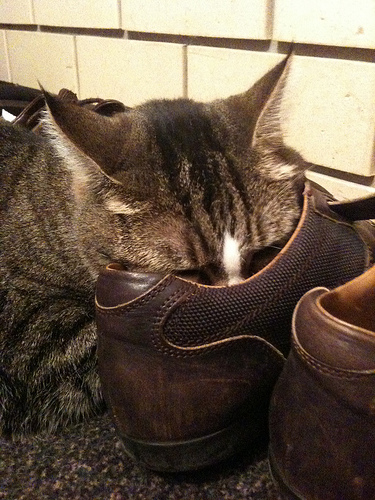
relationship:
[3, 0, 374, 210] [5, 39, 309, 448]
wall behind cat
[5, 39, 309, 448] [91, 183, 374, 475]
cat sniffing shoe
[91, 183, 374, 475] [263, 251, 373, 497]
shoe next to shoe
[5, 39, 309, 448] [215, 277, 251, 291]
cat has nose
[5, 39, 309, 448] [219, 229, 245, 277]
cat has mark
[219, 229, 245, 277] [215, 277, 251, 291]
mark above nose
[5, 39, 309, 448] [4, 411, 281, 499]
cat on rug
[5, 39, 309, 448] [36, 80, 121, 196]
cat has ear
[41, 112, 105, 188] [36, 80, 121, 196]
hair in ear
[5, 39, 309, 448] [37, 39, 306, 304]
cat has head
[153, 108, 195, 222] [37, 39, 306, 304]
stripe on head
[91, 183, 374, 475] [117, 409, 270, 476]
shoe has sole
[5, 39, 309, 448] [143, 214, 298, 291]
cat has face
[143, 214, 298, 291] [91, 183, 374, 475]
face on shoe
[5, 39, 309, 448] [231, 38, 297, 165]
cat has ear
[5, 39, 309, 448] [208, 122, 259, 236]
cat has stripe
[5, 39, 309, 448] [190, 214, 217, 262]
cat has stripe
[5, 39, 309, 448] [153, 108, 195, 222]
cat has stripe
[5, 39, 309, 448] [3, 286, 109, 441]
cat has arm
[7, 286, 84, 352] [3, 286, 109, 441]
stripe on arm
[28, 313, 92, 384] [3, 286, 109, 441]
stripe on arm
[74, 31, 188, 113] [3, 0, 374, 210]
tile on wall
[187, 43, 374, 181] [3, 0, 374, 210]
tile on wall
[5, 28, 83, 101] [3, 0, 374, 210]
tile on wall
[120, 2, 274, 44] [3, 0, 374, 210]
tile on wall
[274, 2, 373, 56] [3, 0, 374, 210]
tile on wall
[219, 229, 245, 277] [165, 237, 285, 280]
mark between eyes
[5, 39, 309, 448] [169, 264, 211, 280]
cat has eye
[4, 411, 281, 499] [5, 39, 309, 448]
rug in front of cat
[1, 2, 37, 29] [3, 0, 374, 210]
block on wall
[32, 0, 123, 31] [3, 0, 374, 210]
block on wall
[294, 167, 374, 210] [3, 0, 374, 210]
block on wall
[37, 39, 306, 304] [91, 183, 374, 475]
head in shoe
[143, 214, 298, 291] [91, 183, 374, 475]
face in shoe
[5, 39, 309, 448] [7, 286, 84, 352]
cat has stripe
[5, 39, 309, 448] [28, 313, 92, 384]
cat has stripe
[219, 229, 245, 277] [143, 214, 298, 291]
mark on face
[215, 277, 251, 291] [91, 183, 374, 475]
nose sniffing shoe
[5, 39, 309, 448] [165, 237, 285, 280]
cat has eyes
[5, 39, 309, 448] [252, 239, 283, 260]
cat has eye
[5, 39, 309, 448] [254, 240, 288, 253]
cat has eyebrow whisker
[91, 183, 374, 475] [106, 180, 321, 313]
shoe has collar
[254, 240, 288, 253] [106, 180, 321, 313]
eyebrow whisker on collar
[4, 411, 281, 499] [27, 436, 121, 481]
rug has yarns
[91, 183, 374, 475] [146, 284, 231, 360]
shoe has seam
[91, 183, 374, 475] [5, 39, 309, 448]
shoe next to cat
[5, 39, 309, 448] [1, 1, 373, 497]
cat in room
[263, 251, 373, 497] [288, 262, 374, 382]
shoe has top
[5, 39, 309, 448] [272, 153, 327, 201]
cat has eyebrow whisker